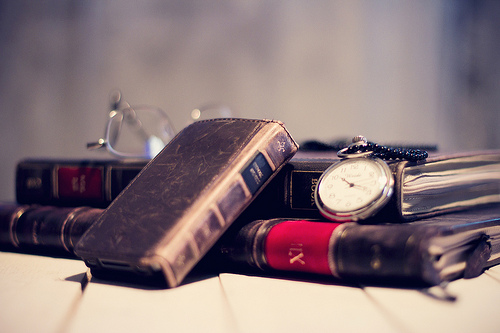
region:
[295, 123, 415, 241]
Clock is on the book.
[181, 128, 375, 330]
Three books are in the table.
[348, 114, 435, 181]
Rope is blue color.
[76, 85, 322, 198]
Eye glass is on the book.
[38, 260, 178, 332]
Table is brown color.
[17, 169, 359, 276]
Letters are golden color.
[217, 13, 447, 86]
Wall is grey color.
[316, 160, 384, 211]
Numbers are in black color.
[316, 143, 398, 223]
Watch is silver and white color.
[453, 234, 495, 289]
book mark is black color.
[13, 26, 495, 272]
These items are antique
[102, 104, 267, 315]
This book is brown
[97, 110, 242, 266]
The book is leather bound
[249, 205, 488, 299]
The book is red and brown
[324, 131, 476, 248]
This is a watch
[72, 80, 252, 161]
these are eyeglasses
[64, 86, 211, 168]
the glasses are for reading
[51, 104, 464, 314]
this could be a library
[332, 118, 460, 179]
The band is rubber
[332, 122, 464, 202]
The watch band is black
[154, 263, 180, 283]
edge of a book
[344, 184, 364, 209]
part of a glass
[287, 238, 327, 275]
edge of a book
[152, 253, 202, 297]
part of a bible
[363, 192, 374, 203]
edge of a clock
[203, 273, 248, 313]
edge of a paper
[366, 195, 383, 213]
edge of a watch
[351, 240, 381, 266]
edge of a book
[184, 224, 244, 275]
edge of a bible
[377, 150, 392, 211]
part of a clock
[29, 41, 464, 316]
These items look vintage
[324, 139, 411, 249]
This is a stop watch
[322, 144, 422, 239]
This stop watch is silver and white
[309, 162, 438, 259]
The clock hands are black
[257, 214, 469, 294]
This book is made of leather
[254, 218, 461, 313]
The book jacket is red and brown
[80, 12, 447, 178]
The background is blurry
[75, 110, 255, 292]
This book is small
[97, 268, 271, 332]
The table is wooden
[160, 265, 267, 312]
The table is light brown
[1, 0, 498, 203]
out of focus background wall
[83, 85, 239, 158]
eyeglasses with silver frames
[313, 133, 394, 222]
antique style silver pocket watch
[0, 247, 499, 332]
beige wooden board table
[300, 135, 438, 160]
black bead watch chain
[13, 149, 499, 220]
antique leather bound book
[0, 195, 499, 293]
antique book with a rounded spine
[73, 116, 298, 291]
small antique leather bound book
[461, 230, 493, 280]
brown ribbon book mark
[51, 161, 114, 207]
red label with gold gilt writing